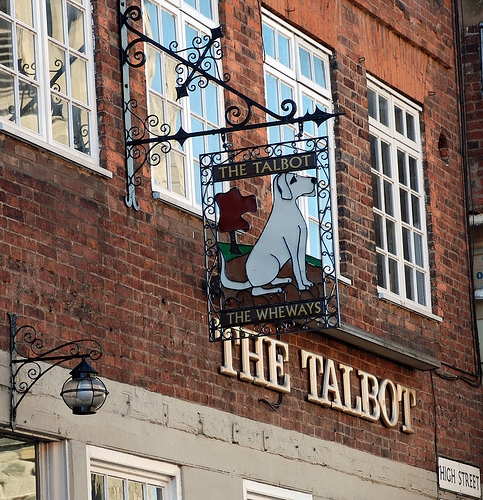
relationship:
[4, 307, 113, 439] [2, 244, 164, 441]
light attached to wall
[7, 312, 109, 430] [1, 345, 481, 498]
lamp on wall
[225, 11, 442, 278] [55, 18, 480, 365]
windows on wall